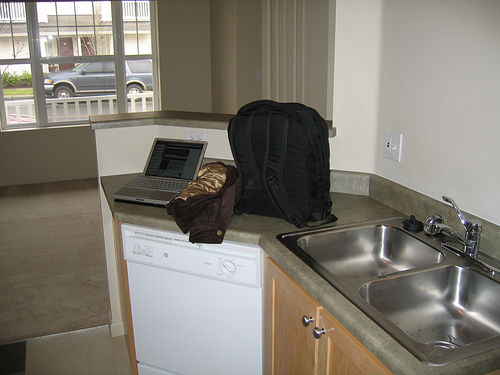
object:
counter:
[99, 172, 406, 245]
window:
[0, 0, 160, 130]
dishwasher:
[120, 222, 265, 375]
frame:
[114, 54, 161, 116]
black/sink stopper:
[401, 215, 424, 233]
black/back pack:
[226, 99, 339, 228]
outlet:
[383, 130, 403, 163]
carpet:
[1, 184, 112, 343]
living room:
[1, 0, 336, 345]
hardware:
[302, 315, 314, 327]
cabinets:
[263, 254, 396, 374]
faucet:
[424, 195, 483, 259]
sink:
[274, 214, 470, 283]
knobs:
[312, 327, 325, 339]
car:
[42, 56, 156, 101]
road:
[7, 94, 160, 114]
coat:
[167, 161, 239, 244]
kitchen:
[90, 0, 500, 370]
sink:
[350, 258, 500, 366]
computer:
[112, 137, 208, 208]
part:
[172, 279, 198, 339]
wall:
[325, 2, 497, 228]